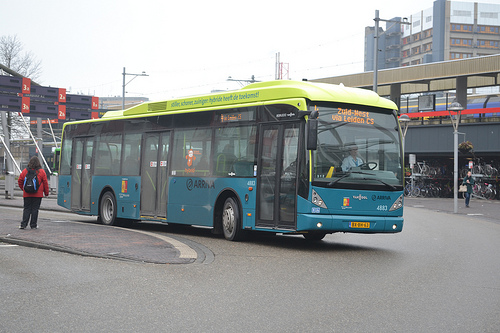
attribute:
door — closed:
[69, 135, 101, 216]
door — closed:
[139, 126, 177, 219]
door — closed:
[255, 121, 303, 232]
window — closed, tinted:
[90, 130, 126, 175]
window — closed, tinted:
[168, 125, 217, 178]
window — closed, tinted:
[210, 124, 258, 178]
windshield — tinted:
[310, 103, 403, 193]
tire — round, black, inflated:
[96, 188, 121, 227]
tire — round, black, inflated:
[217, 193, 245, 242]